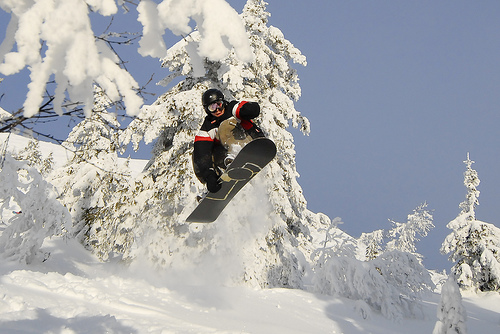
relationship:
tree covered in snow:
[118, 0, 315, 288] [134, 284, 235, 319]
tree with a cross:
[437, 149, 498, 293] [458, 149, 479, 174]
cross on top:
[458, 149, 479, 174] [465, 169, 481, 212]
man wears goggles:
[192, 87, 269, 193] [199, 96, 226, 115]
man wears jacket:
[192, 87, 269, 193] [187, 97, 258, 178]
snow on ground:
[9, 260, 498, 332] [3, 1, 498, 331]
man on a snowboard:
[192, 87, 269, 193] [178, 132, 282, 234]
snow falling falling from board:
[155, 175, 283, 298] [186, 138, 280, 223]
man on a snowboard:
[192, 87, 269, 184] [184, 136, 277, 222]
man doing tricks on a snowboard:
[192, 87, 269, 193] [175, 187, 270, 229]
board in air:
[186, 138, 280, 223] [104, 43, 417, 263]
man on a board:
[192, 87, 269, 193] [186, 138, 280, 223]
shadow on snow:
[3, 300, 135, 332] [106, 297, 199, 323]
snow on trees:
[2, 269, 437, 331] [15, 1, 488, 312]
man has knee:
[192, 87, 269, 193] [213, 118, 238, 136]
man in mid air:
[192, 87, 269, 193] [10, 98, 480, 196]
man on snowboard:
[192, 87, 269, 193] [183, 131, 286, 231]